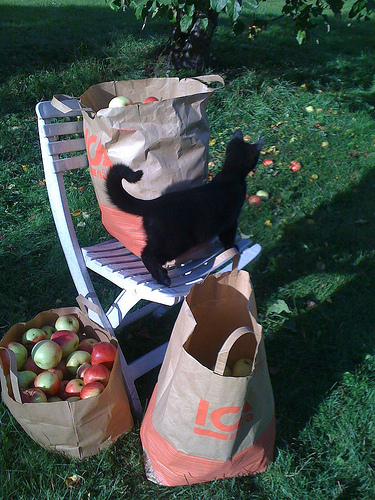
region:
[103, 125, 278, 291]
a black cat standing on a chair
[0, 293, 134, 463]
a paper sack full of apples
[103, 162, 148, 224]
a tail of a black cat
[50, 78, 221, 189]
a paper sack full of apples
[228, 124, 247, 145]
the air of a cat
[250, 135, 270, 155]
the air of a cat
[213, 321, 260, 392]
a handle of a paper sack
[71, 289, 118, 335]
a handle of a paper sack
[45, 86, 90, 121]
a handle of a paper sack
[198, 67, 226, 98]
a handle of a paper sack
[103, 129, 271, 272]
The black cat on the chair.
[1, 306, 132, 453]
Brown bag filled with apples.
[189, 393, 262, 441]
Writing on the paper bag.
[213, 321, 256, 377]
The shopping bag handle.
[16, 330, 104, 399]
The apples in the bag.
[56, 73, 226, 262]
The bag of apples on the chair.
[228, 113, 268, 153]
The cats ears.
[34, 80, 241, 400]
The white plastic chair.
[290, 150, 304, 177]
The red apple.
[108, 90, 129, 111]
The green apple.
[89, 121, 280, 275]
a curious black cat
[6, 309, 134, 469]
a brown paper bag full of apples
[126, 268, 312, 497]
a brown paper bag with a few apples in the bottom of it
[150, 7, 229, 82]
a large tree trunk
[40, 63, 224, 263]
a brown paper bag sitting on a chair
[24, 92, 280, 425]
a folding wooden chair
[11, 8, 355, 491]
lush green grass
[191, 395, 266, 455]
a store logo on the side of a bag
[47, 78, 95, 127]
a handle on a brown paper bag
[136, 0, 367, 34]
leaves from an overhead tree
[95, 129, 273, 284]
BLACK CAT STANDING ON CHAIR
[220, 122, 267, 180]
HEAD OF SMALL CAT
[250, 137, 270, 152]
EAR OF BLACK CAT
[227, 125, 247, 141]
EAR OF BLACK CAT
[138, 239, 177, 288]
LEG OF BLACK CAT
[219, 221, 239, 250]
LEG OF BLACK CAT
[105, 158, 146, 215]
TAIL OF BLACK CAT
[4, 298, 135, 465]
BROWN BAG FULL OF APPLES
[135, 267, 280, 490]
BROWN BAG WITH APPLES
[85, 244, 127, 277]
PART OF WHITE CHAIR SEAT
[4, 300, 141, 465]
the bag is filled with apples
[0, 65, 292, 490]
there are three paper bags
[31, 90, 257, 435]
this is a white folding chair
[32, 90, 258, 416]
a white plastic folding chair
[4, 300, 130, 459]
a paper bag is filled with apples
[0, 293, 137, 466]
a paper bag filled with apples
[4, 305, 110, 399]
the apples are green and red and yellow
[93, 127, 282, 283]
this is a black cat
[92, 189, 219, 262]
there is an orange band stripe on the bag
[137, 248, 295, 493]
this bag is half full with apples